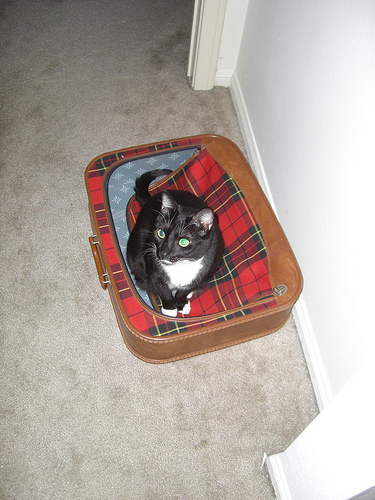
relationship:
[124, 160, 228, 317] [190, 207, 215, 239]
cat has ear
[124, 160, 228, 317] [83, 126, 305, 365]
cat sitting in luggage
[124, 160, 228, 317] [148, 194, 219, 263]
cat has head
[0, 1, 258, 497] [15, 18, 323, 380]
carpet on floor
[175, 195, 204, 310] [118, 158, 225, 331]
hair on cat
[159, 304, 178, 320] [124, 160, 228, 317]
paw on cat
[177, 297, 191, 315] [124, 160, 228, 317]
paw on cat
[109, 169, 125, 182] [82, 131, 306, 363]
design in luggage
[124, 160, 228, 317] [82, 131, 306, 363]
cat inside luggage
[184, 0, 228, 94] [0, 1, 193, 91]
doorway to room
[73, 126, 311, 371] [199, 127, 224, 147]
luggage has zipper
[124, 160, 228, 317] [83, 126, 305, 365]
cat in luggage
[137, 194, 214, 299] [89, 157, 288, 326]
cat in plaid suitcase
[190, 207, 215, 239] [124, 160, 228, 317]
ear on cat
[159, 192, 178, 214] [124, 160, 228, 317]
ear on cat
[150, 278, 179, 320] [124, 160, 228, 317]
leg on cat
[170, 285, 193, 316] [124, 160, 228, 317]
leg on cat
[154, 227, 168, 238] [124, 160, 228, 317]
eye on cat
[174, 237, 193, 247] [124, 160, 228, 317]
eye on cat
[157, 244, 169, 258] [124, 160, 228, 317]
nose on cat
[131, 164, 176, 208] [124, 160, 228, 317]
tail on cat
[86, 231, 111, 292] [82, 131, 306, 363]
handle on luggage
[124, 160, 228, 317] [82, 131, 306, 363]
cat sitting in luggage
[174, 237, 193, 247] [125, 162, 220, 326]
eye on cat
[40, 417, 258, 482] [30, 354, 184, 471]
carpet on floor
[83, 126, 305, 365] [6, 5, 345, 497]
luggage on floor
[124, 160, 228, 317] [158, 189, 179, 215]
cat has ear